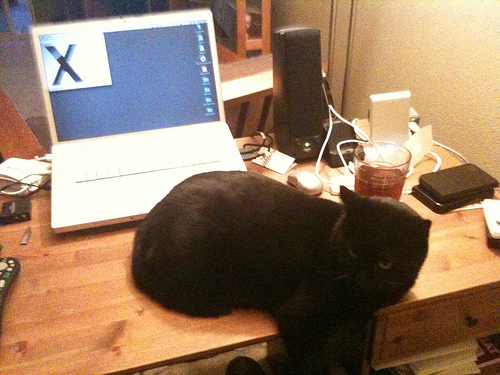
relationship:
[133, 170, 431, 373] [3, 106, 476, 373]
cat on desk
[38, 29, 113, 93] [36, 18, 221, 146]
patch on screen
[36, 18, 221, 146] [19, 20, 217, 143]
screen on computer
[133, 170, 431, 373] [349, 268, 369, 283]
cat has a nose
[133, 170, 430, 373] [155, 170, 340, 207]
black hair on cats back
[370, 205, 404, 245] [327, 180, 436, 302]
hair on cat head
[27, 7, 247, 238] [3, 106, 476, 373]
computer on desk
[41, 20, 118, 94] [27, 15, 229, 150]
x on laptop screen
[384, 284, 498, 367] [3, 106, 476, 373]
drawer built into desk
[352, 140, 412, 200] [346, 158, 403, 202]
glass with liquid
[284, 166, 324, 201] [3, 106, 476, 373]
mouse on desk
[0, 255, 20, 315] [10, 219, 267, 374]
remote on desk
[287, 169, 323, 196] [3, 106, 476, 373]
mouse on desk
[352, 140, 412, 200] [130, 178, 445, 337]
glass next to cat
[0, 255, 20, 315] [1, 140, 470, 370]
remote on desk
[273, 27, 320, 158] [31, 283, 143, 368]
speaker on desk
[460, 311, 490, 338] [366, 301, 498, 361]
knob on drawer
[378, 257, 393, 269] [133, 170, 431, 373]
eye on cat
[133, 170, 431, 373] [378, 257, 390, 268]
cat with eye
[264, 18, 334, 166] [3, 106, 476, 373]
speaker on desk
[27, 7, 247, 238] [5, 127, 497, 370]
computer on desk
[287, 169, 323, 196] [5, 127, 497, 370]
mouse on desk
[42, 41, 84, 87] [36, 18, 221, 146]
x on screen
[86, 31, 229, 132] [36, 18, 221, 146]
background on screen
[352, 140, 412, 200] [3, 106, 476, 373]
glass on desk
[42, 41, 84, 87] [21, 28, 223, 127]
x on background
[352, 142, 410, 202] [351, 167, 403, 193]
glass with liquid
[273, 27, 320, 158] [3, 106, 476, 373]
speaker on desk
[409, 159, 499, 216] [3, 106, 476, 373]
cell phone on desk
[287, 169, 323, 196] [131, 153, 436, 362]
mouse behind cat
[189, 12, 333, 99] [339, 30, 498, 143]
shelf against wall